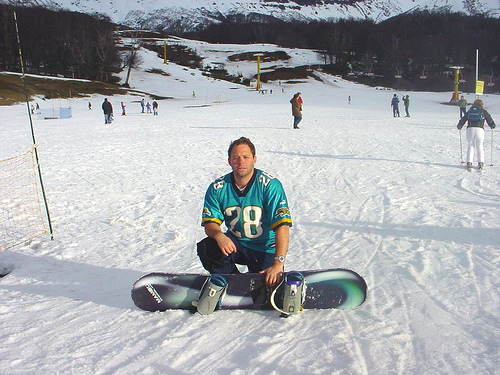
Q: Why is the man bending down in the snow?
A: He is taking a picture.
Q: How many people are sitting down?
A: One.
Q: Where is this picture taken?
A: On a ski slope.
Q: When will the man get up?
A: After he has finished taking the picture.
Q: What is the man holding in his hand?
A: A snowboard.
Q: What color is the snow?
A: White.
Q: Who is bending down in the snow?
A: A man.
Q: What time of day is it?
A: Daytime.